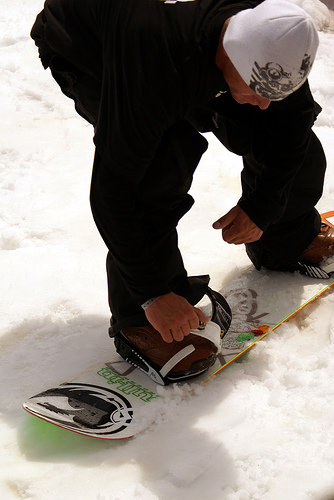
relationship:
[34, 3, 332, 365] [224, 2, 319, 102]
snowboarder wears cap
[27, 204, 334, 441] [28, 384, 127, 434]
snowboard has sticker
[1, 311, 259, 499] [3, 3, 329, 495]
reflection on snow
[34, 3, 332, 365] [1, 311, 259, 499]
snowboarder has shadow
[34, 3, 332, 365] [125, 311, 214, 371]
snowboarder wears boots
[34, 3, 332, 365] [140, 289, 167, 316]
snowboarder wears bracelet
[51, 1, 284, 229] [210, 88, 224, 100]
jacket has zipper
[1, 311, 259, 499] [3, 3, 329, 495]
shadow on snow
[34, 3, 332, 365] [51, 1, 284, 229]
snowboarder wears jacket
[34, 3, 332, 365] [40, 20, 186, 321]
snowboarder wears pants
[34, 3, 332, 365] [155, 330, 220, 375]
snowboarder adjusts straps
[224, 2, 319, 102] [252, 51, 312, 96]
cap has graphics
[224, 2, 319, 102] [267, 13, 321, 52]
cap has seams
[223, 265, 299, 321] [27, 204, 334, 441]
snow on snowboard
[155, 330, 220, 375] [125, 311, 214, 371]
straps above boots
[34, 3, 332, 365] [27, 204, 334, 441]
snowboarder on snowboard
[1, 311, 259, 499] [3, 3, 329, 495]
shadow in snow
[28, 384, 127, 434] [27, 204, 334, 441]
sticker on snowboard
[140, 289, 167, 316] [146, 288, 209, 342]
bracelet on hand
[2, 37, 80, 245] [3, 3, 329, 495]
tracks in snow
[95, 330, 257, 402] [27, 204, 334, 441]
design on snowboard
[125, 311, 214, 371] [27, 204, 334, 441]
boots on snowboard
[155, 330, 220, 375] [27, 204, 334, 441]
straps on snowboard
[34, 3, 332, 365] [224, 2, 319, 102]
snowboarder has cap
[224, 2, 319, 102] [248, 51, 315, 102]
cap has graphics